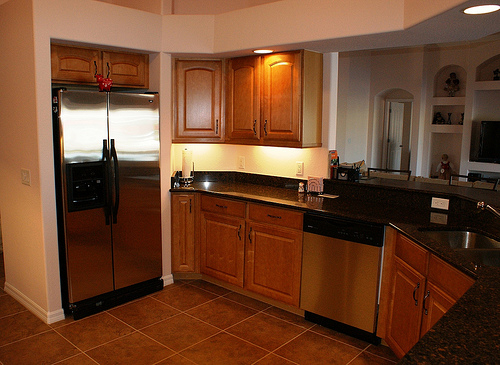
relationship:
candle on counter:
[177, 143, 198, 188] [172, 167, 499, 364]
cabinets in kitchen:
[46, 38, 490, 353] [4, 1, 500, 360]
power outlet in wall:
[293, 164, 304, 177] [171, 51, 342, 288]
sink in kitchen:
[421, 223, 500, 253] [4, 1, 500, 360]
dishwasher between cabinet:
[296, 210, 390, 344] [250, 194, 430, 363]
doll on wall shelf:
[434, 151, 456, 181] [423, 129, 465, 181]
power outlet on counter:
[426, 197, 450, 212] [172, 167, 499, 364]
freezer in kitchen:
[61, 86, 163, 317] [4, 1, 500, 360]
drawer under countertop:
[200, 192, 250, 216] [172, 167, 499, 364]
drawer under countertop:
[248, 200, 303, 235] [172, 167, 499, 364]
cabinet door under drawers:
[199, 210, 249, 289] [199, 193, 305, 244]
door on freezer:
[112, 92, 159, 309] [61, 86, 163, 317]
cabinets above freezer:
[44, 47, 153, 82] [61, 86, 163, 317]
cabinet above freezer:
[53, 45, 100, 83] [61, 86, 163, 317]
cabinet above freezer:
[103, 49, 152, 82] [61, 86, 163, 317]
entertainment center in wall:
[474, 119, 500, 160] [338, 38, 496, 180]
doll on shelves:
[436, 153, 457, 180] [425, 63, 472, 179]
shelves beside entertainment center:
[468, 54, 497, 180] [473, 121, 499, 160]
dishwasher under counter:
[296, 210, 390, 344] [172, 167, 499, 364]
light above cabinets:
[252, 46, 274, 56] [171, 47, 333, 147]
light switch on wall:
[14, 165, 34, 190] [3, 0, 76, 324]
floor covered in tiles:
[6, 287, 393, 358] [2, 272, 425, 362]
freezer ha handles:
[61, 86, 163, 317] [101, 136, 119, 229]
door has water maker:
[56, 81, 116, 322] [67, 161, 110, 215]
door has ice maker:
[56, 81, 116, 322] [66, 160, 105, 214]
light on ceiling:
[252, 46, 274, 56] [35, 0, 500, 52]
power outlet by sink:
[430, 197, 449, 210] [421, 223, 500, 253]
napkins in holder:
[305, 177, 325, 194] [304, 184, 324, 196]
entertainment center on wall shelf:
[469, 119, 499, 163] [468, 93, 500, 167]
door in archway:
[112, 92, 159, 309] [375, 88, 415, 169]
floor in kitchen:
[6, 287, 393, 358] [4, 1, 500, 360]